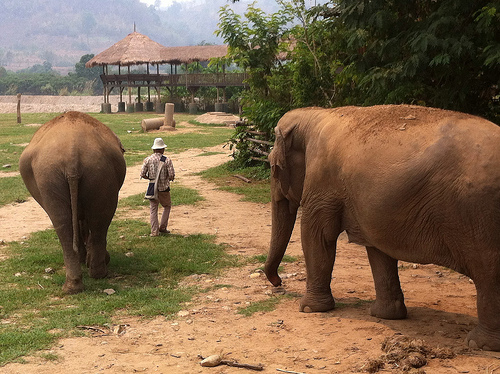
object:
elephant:
[16, 107, 127, 294]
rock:
[244, 260, 265, 279]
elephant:
[257, 103, 497, 352]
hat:
[151, 136, 168, 152]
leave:
[293, 37, 345, 79]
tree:
[222, 6, 297, 132]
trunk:
[260, 179, 303, 288]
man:
[139, 134, 175, 239]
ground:
[129, 312, 243, 371]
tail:
[57, 149, 87, 255]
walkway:
[180, 145, 253, 257]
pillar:
[159, 103, 176, 130]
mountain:
[0, 1, 338, 76]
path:
[174, 142, 250, 218]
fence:
[0, 93, 162, 112]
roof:
[83, 22, 167, 68]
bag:
[142, 157, 166, 200]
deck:
[106, 68, 181, 86]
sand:
[188, 145, 216, 168]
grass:
[128, 117, 142, 130]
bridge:
[182, 71, 246, 112]